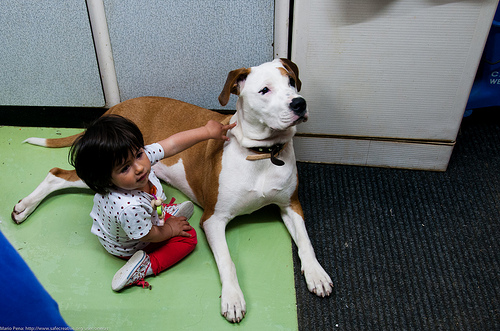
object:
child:
[70, 127, 202, 283]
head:
[70, 116, 150, 191]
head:
[219, 55, 309, 130]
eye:
[119, 157, 134, 178]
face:
[67, 86, 242, 301]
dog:
[14, 50, 391, 326]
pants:
[140, 210, 203, 267]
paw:
[295, 255, 342, 304]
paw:
[211, 282, 251, 324]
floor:
[297, 102, 498, 330]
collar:
[225, 137, 325, 169]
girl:
[70, 116, 236, 291]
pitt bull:
[3, 41, 348, 329]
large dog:
[10, 52, 338, 322]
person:
[52, 114, 258, 295]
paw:
[8, 191, 39, 229]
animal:
[9, 49, 341, 330]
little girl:
[68, 115, 240, 292]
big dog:
[7, 57, 340, 329]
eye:
[133, 150, 145, 160]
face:
[112, 145, 156, 186]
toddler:
[44, 95, 257, 311]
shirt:
[67, 146, 179, 253]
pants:
[153, 216, 201, 270]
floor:
[4, 118, 481, 329]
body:
[68, 110, 182, 262]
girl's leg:
[127, 217, 202, 287]